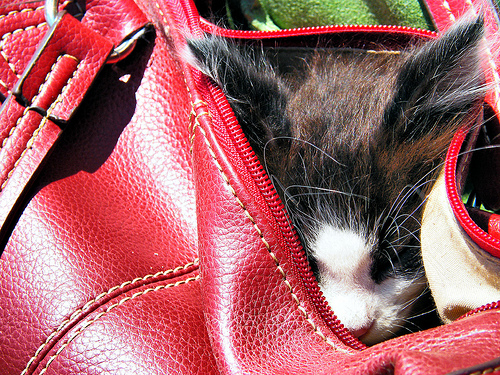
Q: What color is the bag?
A: Red.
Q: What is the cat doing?
A: Sitting in a bag.